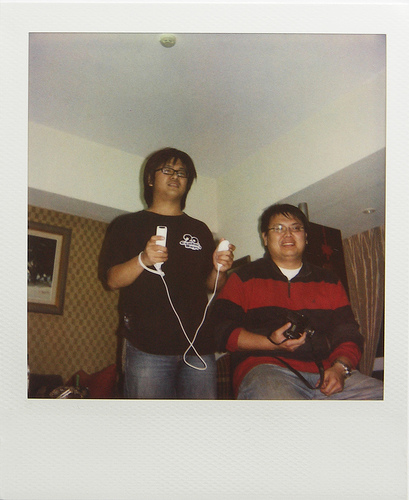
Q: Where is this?
A: This is at the living room.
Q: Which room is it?
A: It is a living room.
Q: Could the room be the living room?
A: Yes, it is the living room.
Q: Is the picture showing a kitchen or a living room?
A: It is showing a living room.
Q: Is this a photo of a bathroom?
A: No, the picture is showing a living room.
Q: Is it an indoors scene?
A: Yes, it is indoors.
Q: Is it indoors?
A: Yes, it is indoors.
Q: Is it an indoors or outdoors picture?
A: It is indoors.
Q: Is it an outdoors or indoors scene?
A: It is indoors.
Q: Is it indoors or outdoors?
A: It is indoors.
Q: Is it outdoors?
A: No, it is indoors.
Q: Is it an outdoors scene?
A: No, it is indoors.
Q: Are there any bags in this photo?
A: No, there are no bags.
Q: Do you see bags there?
A: No, there are no bags.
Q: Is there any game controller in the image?
A: Yes, there is a game controller.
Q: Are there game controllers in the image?
A: Yes, there is a game controller.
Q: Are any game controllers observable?
A: Yes, there is a game controller.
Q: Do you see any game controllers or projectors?
A: Yes, there is a game controller.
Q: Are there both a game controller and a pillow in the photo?
A: Yes, there are both a game controller and a pillow.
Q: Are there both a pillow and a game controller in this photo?
A: Yes, there are both a game controller and a pillow.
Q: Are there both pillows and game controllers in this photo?
A: Yes, there are both a game controller and a pillow.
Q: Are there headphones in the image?
A: No, there are no headphones.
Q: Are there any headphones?
A: No, there are no headphones.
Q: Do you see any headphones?
A: No, there are no headphones.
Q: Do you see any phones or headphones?
A: No, there are no headphones or phones.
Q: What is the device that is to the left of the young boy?
A: The device is a game controller.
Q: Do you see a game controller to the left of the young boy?
A: Yes, there is a game controller to the left of the boy.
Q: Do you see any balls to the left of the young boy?
A: No, there is a game controller to the left of the boy.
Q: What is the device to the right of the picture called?
A: The device is a game controller.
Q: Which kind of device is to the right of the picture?
A: The device is a game controller.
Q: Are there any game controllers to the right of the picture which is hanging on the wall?
A: Yes, there is a game controller to the right of the picture.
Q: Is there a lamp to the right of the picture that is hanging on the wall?
A: No, there is a game controller to the right of the picture.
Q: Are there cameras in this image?
A: Yes, there is a camera.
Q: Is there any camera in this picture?
A: Yes, there is a camera.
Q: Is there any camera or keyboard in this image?
A: Yes, there is a camera.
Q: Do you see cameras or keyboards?
A: Yes, there is a camera.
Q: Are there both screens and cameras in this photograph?
A: No, there is a camera but no screens.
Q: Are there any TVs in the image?
A: No, there are no tvs.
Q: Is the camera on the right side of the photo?
A: Yes, the camera is on the right of the image.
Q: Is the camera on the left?
A: No, the camera is on the right of the image.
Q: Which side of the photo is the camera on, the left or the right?
A: The camera is on the right of the image.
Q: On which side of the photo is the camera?
A: The camera is on the right of the image.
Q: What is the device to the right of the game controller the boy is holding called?
A: The device is a camera.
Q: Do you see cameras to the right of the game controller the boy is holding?
A: Yes, there is a camera to the right of the game controller.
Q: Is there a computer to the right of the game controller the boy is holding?
A: No, there is a camera to the right of the game controller.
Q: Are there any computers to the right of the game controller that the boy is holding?
A: No, there is a camera to the right of the game controller.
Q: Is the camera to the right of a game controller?
A: Yes, the camera is to the right of a game controller.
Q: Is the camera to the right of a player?
A: No, the camera is to the right of a game controller.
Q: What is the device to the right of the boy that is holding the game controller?
A: The device is a camera.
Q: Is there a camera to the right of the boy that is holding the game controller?
A: Yes, there is a camera to the right of the boy.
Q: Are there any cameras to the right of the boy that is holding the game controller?
A: Yes, there is a camera to the right of the boy.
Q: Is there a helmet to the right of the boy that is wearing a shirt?
A: No, there is a camera to the right of the boy.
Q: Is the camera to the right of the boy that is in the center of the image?
A: Yes, the camera is to the right of the boy.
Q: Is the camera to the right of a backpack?
A: No, the camera is to the right of the boy.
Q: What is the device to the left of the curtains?
A: The device is a camera.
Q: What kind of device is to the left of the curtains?
A: The device is a camera.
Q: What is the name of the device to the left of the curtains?
A: The device is a camera.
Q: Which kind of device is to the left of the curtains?
A: The device is a camera.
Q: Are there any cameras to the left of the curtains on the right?
A: Yes, there is a camera to the left of the curtains.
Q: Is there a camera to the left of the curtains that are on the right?
A: Yes, there is a camera to the left of the curtains.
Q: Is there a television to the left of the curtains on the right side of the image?
A: No, there is a camera to the left of the curtains.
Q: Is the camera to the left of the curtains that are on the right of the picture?
A: Yes, the camera is to the left of the curtains.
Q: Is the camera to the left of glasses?
A: No, the camera is to the left of the curtains.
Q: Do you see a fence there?
A: No, there are no fences.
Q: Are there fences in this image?
A: No, there are no fences.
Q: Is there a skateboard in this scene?
A: No, there are no skateboards.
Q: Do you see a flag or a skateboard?
A: No, there are no skateboards or flags.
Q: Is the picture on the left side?
A: Yes, the picture is on the left of the image.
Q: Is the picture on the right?
A: No, the picture is on the left of the image.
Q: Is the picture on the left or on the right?
A: The picture is on the left of the image.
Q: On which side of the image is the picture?
A: The picture is on the left of the image.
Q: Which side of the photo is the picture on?
A: The picture is on the left of the image.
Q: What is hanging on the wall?
A: The picture is hanging on the wall.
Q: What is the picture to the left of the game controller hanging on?
A: The picture is hanging on the wall.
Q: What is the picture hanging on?
A: The picture is hanging on the wall.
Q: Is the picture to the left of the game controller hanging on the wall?
A: Yes, the picture is hanging on the wall.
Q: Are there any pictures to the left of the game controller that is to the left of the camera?
A: Yes, there is a picture to the left of the game controller.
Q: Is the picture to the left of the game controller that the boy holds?
A: Yes, the picture is to the left of the game controller.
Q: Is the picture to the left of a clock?
A: No, the picture is to the left of the game controller.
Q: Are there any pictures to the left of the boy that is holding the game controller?
A: Yes, there is a picture to the left of the boy.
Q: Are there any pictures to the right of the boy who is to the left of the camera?
A: No, the picture is to the left of the boy.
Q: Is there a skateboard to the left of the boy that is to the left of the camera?
A: No, there is a picture to the left of the boy.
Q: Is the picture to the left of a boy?
A: Yes, the picture is to the left of a boy.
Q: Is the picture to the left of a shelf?
A: No, the picture is to the left of a boy.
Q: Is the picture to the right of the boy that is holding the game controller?
A: No, the picture is to the left of the boy.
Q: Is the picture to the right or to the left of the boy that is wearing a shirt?
A: The picture is to the left of the boy.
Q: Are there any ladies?
A: No, there are no ladies.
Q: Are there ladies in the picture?
A: No, there are no ladies.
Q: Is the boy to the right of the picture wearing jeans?
A: Yes, the boy is wearing jeans.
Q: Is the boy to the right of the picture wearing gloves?
A: No, the boy is wearing jeans.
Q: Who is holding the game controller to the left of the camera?
A: The boy is holding the game controller.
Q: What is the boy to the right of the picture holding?
A: The boy is holding the game controller.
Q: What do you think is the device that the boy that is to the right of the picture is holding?
A: The device is a game controller.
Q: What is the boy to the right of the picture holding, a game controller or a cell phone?
A: The boy is holding a game controller.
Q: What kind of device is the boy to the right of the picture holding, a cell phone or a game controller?
A: The boy is holding a game controller.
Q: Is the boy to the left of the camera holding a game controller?
A: Yes, the boy is holding a game controller.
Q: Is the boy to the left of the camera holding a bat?
A: No, the boy is holding a game controller.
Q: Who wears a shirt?
A: The boy wears a shirt.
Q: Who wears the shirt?
A: The boy wears a shirt.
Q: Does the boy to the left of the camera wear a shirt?
A: Yes, the boy wears a shirt.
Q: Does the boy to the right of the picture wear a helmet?
A: No, the boy wears a shirt.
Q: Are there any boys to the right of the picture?
A: Yes, there is a boy to the right of the picture.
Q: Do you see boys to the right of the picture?
A: Yes, there is a boy to the right of the picture.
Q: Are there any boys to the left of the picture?
A: No, the boy is to the right of the picture.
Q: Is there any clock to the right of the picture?
A: No, there is a boy to the right of the picture.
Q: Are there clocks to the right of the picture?
A: No, there is a boy to the right of the picture.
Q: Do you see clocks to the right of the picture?
A: No, there is a boy to the right of the picture.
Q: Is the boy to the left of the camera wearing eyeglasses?
A: Yes, the boy is wearing eyeglasses.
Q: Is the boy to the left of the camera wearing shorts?
A: No, the boy is wearing eyeglasses.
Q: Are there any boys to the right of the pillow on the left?
A: Yes, there is a boy to the right of the pillow.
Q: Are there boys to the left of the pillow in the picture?
A: No, the boy is to the right of the pillow.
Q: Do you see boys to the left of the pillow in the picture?
A: No, the boy is to the right of the pillow.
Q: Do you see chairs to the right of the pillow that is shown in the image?
A: No, there is a boy to the right of the pillow.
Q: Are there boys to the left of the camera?
A: Yes, there is a boy to the left of the camera.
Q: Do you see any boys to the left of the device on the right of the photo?
A: Yes, there is a boy to the left of the camera.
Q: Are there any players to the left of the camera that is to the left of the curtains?
A: No, there is a boy to the left of the camera.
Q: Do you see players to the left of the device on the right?
A: No, there is a boy to the left of the camera.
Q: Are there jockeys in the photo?
A: No, there are no jockeys.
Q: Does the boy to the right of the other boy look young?
A: Yes, the boy is young.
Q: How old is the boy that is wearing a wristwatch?
A: The boy is young.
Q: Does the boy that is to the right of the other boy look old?
A: No, the boy is young.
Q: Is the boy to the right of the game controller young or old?
A: The boy is young.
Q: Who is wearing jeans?
A: The boy is wearing jeans.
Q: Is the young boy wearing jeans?
A: Yes, the boy is wearing jeans.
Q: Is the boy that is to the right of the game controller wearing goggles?
A: No, the boy is wearing jeans.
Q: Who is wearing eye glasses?
A: The boy is wearing eye glasses.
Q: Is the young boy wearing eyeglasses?
A: Yes, the boy is wearing eyeglasses.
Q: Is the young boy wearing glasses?
A: No, the boy is wearing eyeglasses.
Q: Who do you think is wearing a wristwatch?
A: The boy is wearing a wristwatch.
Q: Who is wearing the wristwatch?
A: The boy is wearing a wristwatch.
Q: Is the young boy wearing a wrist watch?
A: Yes, the boy is wearing a wrist watch.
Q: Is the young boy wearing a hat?
A: No, the boy is wearing a wrist watch.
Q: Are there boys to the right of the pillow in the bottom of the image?
A: Yes, there is a boy to the right of the pillow.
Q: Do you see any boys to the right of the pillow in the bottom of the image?
A: Yes, there is a boy to the right of the pillow.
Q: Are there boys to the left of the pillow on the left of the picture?
A: No, the boy is to the right of the pillow.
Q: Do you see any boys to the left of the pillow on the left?
A: No, the boy is to the right of the pillow.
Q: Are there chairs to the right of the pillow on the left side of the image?
A: No, there is a boy to the right of the pillow.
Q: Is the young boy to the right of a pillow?
A: Yes, the boy is to the right of a pillow.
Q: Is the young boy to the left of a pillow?
A: No, the boy is to the right of a pillow.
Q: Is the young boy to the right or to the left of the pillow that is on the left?
A: The boy is to the right of the pillow.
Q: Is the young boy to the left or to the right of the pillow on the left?
A: The boy is to the right of the pillow.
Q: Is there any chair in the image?
A: No, there are no chairs.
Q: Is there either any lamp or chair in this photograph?
A: No, there are no chairs or lamps.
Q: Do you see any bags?
A: No, there are no bags.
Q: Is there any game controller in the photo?
A: Yes, there is a game controller.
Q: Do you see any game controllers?
A: Yes, there is a game controller.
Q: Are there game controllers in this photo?
A: Yes, there is a game controller.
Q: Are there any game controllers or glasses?
A: Yes, there is a game controller.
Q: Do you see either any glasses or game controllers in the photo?
A: Yes, there is a game controller.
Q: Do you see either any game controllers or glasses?
A: Yes, there is a game controller.